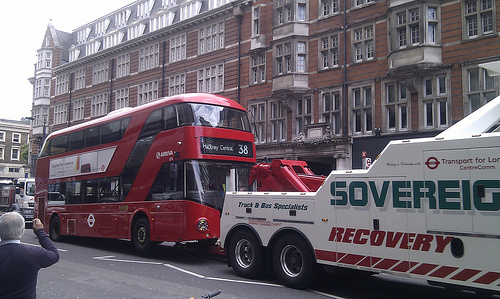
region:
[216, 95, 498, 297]
white two truck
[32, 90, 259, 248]
red double-decker bus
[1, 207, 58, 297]
man taking picture of red bus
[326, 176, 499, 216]
name of towtruck company in green writing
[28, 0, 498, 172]
brick building beside road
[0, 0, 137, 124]
white cloudy sky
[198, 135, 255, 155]
identification sign and number of bus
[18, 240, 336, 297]
white lines on road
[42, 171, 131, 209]
clear glass passenger windows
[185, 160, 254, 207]
driver's windshield on bus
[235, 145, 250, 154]
The number 38 on the double level bus.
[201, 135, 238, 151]
The white letters in the display window on the front of the bus.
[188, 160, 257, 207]
The front lower level window of the bus.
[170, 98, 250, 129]
The top level front window of the bus.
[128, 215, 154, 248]
The front wheel of the bus.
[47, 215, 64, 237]
The back wheel of the bus.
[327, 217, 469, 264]
The word Recovery on the tow truck.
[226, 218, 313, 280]
The back wheels of the tow truck.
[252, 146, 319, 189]
The red mechanism on the back of the tow truck.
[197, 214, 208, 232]
The front headlight of the bus.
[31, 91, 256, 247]
a large red bus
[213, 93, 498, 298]
part of a tow truck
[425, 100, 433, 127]
a window of a building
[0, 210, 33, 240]
a man's gray hair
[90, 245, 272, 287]
a long white line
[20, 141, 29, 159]
part of a green tree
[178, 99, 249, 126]
the window of a bus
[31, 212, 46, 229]
the hand of a man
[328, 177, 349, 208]
a large capital green letter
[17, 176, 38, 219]
part of a white truck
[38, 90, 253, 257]
the bus is a double decker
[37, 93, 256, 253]
the bus is red in color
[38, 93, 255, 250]
the bus is shiny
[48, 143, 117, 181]
a sign runs along the side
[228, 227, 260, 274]
the tire is black in color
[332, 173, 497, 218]
the truck has lettering on the side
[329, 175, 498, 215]
the lettering is blue in color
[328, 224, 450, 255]
the lettering is red in color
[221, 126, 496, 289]
the tow truck is painted white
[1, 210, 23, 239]
the man's hair is grey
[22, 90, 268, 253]
double decker bus for passengers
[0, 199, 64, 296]
man on the street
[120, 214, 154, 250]
wheel of double decker bus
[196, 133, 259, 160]
area for bus route and number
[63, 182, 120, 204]
side windows on lower level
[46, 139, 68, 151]
side window on upper level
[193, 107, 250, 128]
upper level front window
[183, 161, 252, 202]
lower level front window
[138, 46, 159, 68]
window on building on street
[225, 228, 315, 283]
wheels on other vehicle